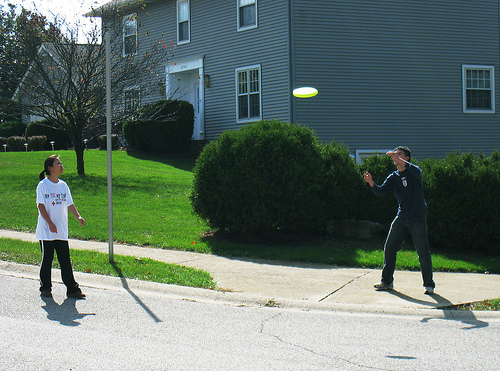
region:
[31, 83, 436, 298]
Two people playing Frisbee.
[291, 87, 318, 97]
Yellow Frisbee in the air.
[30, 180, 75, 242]
Girl wearing white shirt.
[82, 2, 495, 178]
Tall blue house.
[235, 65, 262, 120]
White painted framed window.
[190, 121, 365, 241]
Big leafy green bush.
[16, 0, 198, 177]
No leaves on the tree.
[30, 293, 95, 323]
Gray shadow on the road.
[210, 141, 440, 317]
Man standing on the corner.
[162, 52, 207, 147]
White trimmed door way.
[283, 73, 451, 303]
a man getting ready to catch a frisbee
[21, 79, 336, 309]
A woman watching a frisbee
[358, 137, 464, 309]
a man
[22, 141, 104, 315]
a woman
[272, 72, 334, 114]
a Frisbee in the air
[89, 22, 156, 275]
a pole next to a sidewalk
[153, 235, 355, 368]
a sidewalk next to a road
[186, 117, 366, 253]
a bush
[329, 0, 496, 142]
a window on the side of a gray house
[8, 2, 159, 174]
A tree in a yard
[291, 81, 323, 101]
Yellow frisbee flying in the air.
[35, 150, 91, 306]
Woman playing frisbee with a guy.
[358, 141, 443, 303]
Guy waiting to catch the yellow flying frisbee.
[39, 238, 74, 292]
Black pants worn by woman playing frisbee.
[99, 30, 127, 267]
Tall street pole next to the woman playing frisbee.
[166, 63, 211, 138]
Front door of big gray house.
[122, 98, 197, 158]
Green round bush in front of door of big gray house.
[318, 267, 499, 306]
Sidewalk guy playing frisbee is standing on.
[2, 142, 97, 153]
Small light fixtures on driveway leading to big gray house.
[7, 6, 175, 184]
Tree with no leaves on it in front of big gray house.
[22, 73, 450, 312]
people playing with a Frisbee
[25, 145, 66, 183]
woman wearing her hair in a ponytail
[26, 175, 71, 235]
woman wearing white shirt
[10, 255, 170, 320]
woman standing on street near curb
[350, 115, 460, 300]
man standing on sidewalk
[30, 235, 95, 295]
woman wearing dark pants with white stripe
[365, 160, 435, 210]
man wearing dark shirt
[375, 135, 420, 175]
man's left arm partially obscuring his face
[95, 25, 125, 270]
tall pole near sidewalk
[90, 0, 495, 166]
large building with grey siding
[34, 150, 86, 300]
brown haired short woman playing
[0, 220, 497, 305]
paved narrow tan sidewalk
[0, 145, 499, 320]
very green cut grass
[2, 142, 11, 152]
small solar powered lawn lamp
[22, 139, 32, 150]
small solar powered lawn lamp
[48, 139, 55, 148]
small solar powered lawn lamp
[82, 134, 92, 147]
small solar powered lawn lamp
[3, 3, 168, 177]
small young bare tree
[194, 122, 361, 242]
well manicured green wide bush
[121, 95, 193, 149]
well manicured green wide bush